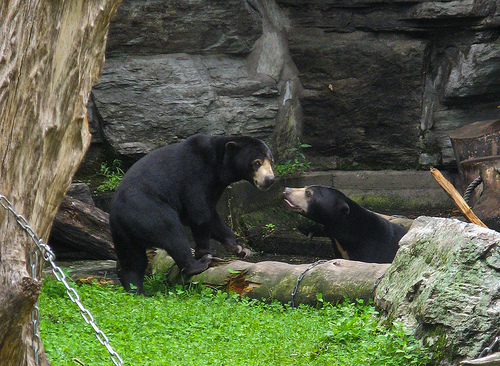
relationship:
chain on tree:
[1, 196, 134, 365] [0, 2, 108, 365]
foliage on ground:
[91, 288, 375, 359] [14, 227, 499, 362]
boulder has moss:
[375, 218, 499, 365] [438, 245, 482, 316]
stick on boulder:
[428, 160, 493, 236] [375, 218, 499, 365]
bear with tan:
[110, 132, 272, 292] [258, 159, 275, 195]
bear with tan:
[285, 185, 429, 272] [283, 185, 307, 212]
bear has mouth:
[285, 185, 429, 272] [279, 188, 316, 221]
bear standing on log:
[110, 132, 272, 292] [71, 207, 393, 315]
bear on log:
[110, 132, 272, 292] [71, 207, 393, 315]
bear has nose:
[110, 132, 272, 292] [262, 175, 277, 187]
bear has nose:
[285, 185, 429, 272] [278, 186, 289, 196]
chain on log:
[282, 254, 333, 310] [71, 207, 393, 315]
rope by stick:
[460, 172, 484, 211] [428, 160, 493, 236]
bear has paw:
[110, 132, 272, 292] [228, 229, 252, 263]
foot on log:
[171, 249, 221, 282] [71, 207, 393, 315]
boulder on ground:
[375, 218, 499, 365] [14, 227, 499, 362]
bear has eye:
[110, 132, 272, 292] [254, 159, 260, 167]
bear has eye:
[285, 185, 429, 272] [306, 189, 310, 199]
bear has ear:
[110, 132, 272, 292] [221, 141, 238, 155]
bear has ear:
[285, 185, 429, 272] [339, 203, 351, 220]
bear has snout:
[110, 132, 272, 292] [246, 161, 276, 192]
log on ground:
[71, 207, 393, 315] [14, 227, 499, 362]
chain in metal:
[1, 196, 134, 365] [7, 204, 29, 225]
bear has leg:
[110, 132, 272, 292] [122, 199, 209, 280]